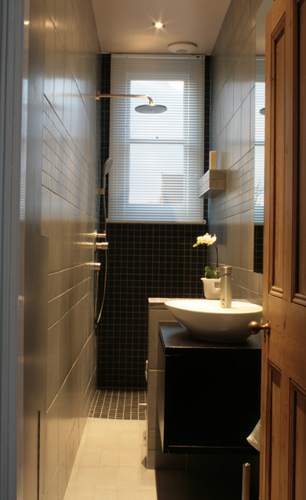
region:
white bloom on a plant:
[192, 228, 216, 249]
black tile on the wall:
[117, 236, 176, 281]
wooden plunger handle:
[239, 461, 251, 498]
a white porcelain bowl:
[164, 294, 264, 336]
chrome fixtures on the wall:
[91, 225, 110, 271]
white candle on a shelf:
[206, 147, 220, 167]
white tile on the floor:
[90, 422, 136, 477]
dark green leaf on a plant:
[203, 265, 214, 276]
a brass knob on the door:
[249, 319, 269, 333]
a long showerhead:
[103, 87, 162, 118]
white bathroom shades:
[115, 53, 204, 214]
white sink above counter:
[167, 294, 247, 338]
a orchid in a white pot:
[189, 221, 246, 287]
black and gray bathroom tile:
[115, 255, 141, 316]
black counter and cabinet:
[155, 332, 256, 494]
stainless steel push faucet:
[200, 265, 248, 323]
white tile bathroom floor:
[102, 424, 130, 478]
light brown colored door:
[270, 318, 288, 429]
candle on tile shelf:
[199, 139, 232, 172]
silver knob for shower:
[89, 224, 125, 335]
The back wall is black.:
[115, 235, 201, 276]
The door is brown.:
[259, 308, 305, 361]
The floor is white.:
[84, 470, 139, 495]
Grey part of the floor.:
[97, 393, 152, 405]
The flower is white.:
[191, 228, 221, 258]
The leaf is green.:
[198, 264, 223, 279]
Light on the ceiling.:
[131, 8, 174, 30]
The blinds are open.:
[119, 181, 213, 222]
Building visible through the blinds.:
[156, 171, 196, 206]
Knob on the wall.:
[72, 240, 117, 261]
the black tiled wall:
[109, 223, 141, 290]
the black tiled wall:
[145, 227, 206, 278]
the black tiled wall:
[121, 287, 151, 348]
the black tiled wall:
[131, 266, 187, 283]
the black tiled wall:
[105, 270, 152, 346]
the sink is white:
[163, 286, 259, 329]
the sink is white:
[151, 297, 296, 341]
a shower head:
[92, 83, 174, 121]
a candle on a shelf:
[203, 143, 219, 170]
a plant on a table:
[185, 229, 221, 297]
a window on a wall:
[105, 51, 209, 227]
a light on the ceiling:
[141, 14, 169, 31]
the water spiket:
[214, 261, 237, 315]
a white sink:
[163, 294, 268, 340]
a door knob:
[244, 316, 275, 334]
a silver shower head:
[96, 148, 112, 224]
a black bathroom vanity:
[155, 316, 262, 463]